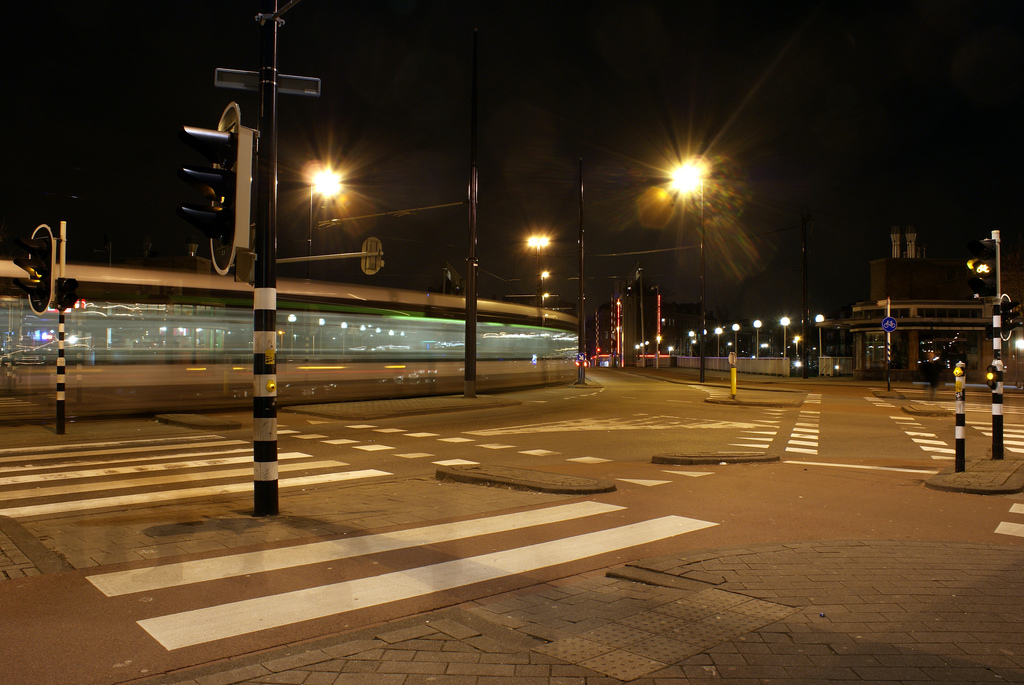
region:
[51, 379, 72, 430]
pole on the ground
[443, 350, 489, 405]
pole on the ground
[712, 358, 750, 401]
pole on the ground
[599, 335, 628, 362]
pole on the ground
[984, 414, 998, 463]
pole on the ground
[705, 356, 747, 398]
pole on the ground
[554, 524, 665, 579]
line on the road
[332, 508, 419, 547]
line on the road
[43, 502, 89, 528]
line on the road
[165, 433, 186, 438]
line on the road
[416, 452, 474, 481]
line on the road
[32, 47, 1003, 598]
a scene at night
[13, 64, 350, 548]
couple of black and white poles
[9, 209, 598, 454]
a clear building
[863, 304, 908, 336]
a blue sign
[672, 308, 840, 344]
Street lights along bridge.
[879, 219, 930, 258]
Chimneys on rooftop.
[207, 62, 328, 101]
Street sign on post.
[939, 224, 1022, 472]
Black and white striped posts in center of street.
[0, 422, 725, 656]
Crosswalk in street.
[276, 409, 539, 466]
White squares painted in street.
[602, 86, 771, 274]
Halo around street light.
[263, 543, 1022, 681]
Brick sidewalk next to street.